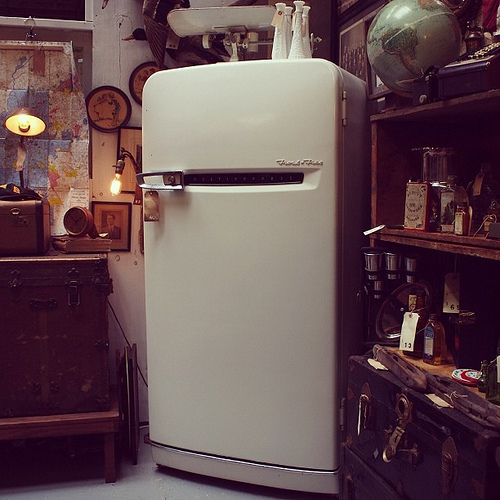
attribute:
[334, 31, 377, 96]
photo — aged, group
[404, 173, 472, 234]
bottles — old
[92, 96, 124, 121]
picture — aged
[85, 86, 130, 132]
frame — round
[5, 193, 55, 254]
chest — brown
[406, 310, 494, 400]
antique — small, decorative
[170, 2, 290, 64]
scale — old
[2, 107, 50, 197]
light — on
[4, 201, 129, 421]
trunks — old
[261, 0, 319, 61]
four vases — glass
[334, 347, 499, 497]
chest — black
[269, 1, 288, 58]
vase — four, white, milk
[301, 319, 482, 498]
trunk — old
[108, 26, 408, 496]
fridge — white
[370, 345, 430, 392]
antique — small, decorative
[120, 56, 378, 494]
refrigerator — is big, is white, old, timey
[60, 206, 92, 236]
alarm clock — red, old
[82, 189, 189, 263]
frame — black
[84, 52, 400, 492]
fridge — white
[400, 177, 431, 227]
antique — decorative, small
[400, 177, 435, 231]
antique — small, decorative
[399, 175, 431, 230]
antique — small, decorative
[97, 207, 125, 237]
photo — aged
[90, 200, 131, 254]
frame — wooden, picture